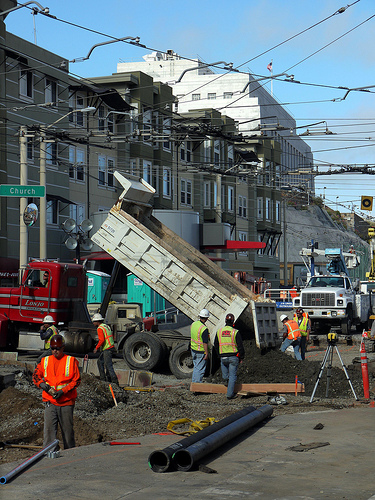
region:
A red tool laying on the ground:
[98, 430, 149, 461]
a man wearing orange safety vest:
[34, 343, 95, 429]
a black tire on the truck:
[122, 308, 192, 393]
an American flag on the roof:
[261, 56, 285, 105]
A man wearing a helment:
[78, 304, 138, 390]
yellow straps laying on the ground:
[167, 402, 227, 451]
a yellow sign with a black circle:
[355, 184, 373, 218]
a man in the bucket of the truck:
[334, 228, 369, 288]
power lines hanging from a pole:
[28, 94, 149, 178]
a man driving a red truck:
[22, 256, 81, 328]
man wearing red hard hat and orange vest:
[34, 332, 77, 447]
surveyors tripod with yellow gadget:
[309, 332, 356, 403]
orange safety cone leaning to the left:
[358, 340, 371, 405]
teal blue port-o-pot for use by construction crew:
[87, 268, 107, 304]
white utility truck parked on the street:
[291, 247, 373, 330]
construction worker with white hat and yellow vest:
[189, 305, 210, 387]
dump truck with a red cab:
[1, 204, 280, 377]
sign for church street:
[0, 181, 49, 199]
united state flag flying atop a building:
[267, 56, 276, 96]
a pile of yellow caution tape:
[165, 414, 219, 439]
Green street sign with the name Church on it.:
[0, 175, 50, 206]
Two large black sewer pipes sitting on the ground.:
[143, 395, 281, 475]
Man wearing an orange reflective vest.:
[34, 331, 90, 451]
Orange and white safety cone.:
[354, 338, 372, 386]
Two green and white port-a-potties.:
[80, 266, 180, 329]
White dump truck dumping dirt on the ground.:
[90, 164, 317, 397]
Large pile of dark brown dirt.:
[200, 308, 374, 400]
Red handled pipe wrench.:
[95, 438, 143, 452]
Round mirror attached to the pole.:
[17, 199, 42, 226]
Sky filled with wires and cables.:
[38, 36, 369, 216]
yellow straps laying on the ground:
[170, 407, 219, 434]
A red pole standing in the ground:
[355, 345, 372, 412]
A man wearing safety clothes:
[38, 334, 88, 419]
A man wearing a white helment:
[189, 304, 222, 353]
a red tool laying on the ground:
[93, 429, 163, 469]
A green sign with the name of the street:
[2, 171, 66, 207]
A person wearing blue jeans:
[218, 340, 261, 411]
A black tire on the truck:
[116, 309, 174, 387]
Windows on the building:
[52, 137, 118, 201]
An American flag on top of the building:
[255, 54, 290, 100]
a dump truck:
[7, 186, 280, 368]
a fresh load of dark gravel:
[214, 334, 359, 403]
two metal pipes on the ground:
[138, 393, 289, 480]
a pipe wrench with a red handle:
[99, 435, 144, 451]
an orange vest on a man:
[35, 353, 86, 405]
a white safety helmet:
[197, 308, 211, 319]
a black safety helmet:
[48, 331, 71, 343]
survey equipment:
[303, 323, 367, 405]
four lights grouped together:
[55, 216, 98, 251]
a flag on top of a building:
[266, 57, 276, 79]